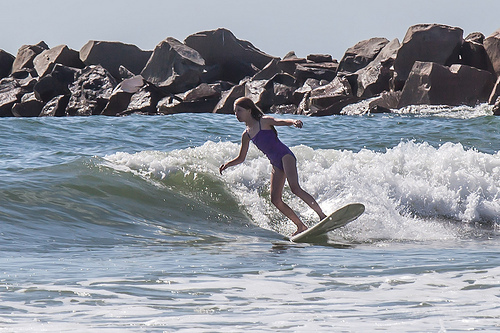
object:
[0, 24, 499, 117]
boulders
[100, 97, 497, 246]
surf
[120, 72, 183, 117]
animal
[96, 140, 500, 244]
break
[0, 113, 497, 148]
slope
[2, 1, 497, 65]
sky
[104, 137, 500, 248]
breakwater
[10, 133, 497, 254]
wave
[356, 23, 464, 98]
rock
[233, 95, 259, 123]
head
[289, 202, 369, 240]
surfboard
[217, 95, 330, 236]
girl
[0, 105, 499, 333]
ocean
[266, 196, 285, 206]
knees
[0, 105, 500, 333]
water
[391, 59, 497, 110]
rocks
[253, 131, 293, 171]
swimsuit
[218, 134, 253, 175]
arms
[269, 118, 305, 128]
arms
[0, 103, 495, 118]
beach